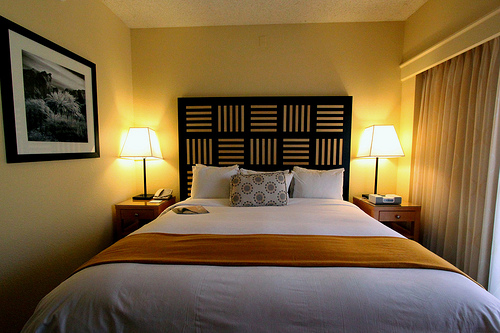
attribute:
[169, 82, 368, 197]
headboard — black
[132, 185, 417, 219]
tables — small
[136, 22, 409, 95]
wall — yellow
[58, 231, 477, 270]
sheet — orange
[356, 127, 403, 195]
table lamp — illuminated, white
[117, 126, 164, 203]
table lamp — illuminated, white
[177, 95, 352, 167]
headboard — black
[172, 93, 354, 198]
headboard — ornate, dark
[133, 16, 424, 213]
wall — pale yellow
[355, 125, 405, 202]
lampshade — white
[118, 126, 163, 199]
lampshade — white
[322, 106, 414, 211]
lamp — on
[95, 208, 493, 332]
bedsheets — white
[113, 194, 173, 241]
brown drawer — wooden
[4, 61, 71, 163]
photograph — big, framed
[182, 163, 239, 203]
pillow — white, fluffy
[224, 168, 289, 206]
pillow — grey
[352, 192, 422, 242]
table — brown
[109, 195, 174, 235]
table — brown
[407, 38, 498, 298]
drape — floor length